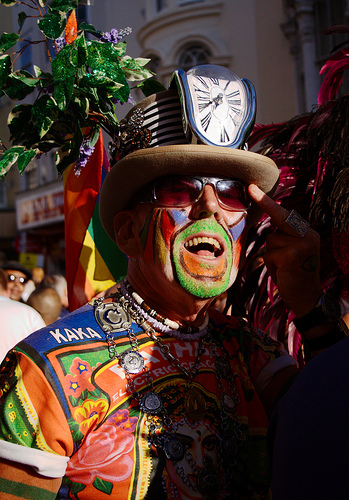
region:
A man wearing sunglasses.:
[149, 175, 240, 213]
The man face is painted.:
[148, 190, 247, 297]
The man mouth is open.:
[172, 229, 227, 266]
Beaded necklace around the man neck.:
[110, 292, 203, 354]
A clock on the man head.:
[172, 65, 256, 137]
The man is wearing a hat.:
[102, 84, 253, 175]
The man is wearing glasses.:
[3, 270, 23, 284]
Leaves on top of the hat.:
[44, 37, 139, 106]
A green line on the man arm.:
[8, 477, 38, 498]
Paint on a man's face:
[136, 163, 254, 299]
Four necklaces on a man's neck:
[91, 273, 241, 498]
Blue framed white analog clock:
[178, 63, 256, 148]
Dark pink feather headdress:
[236, 45, 347, 360]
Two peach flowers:
[63, 355, 92, 397]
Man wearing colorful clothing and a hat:
[0, 64, 347, 498]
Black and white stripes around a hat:
[141, 94, 189, 148]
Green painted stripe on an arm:
[0, 473, 62, 497]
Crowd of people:
[0, 255, 69, 370]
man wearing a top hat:
[97, 93, 278, 299]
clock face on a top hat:
[185, 59, 250, 146]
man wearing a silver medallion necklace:
[93, 295, 243, 492]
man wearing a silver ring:
[282, 210, 310, 239]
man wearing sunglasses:
[128, 171, 259, 212]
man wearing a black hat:
[1, 259, 34, 279]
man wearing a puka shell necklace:
[117, 278, 210, 340]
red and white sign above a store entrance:
[13, 182, 64, 224]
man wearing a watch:
[286, 291, 343, 337]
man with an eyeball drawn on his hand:
[300, 251, 321, 271]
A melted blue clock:
[170, 54, 258, 151]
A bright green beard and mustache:
[166, 210, 236, 302]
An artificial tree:
[0, 1, 157, 170]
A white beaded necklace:
[111, 272, 218, 345]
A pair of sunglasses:
[149, 179, 238, 213]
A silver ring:
[282, 202, 311, 241]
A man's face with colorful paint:
[123, 158, 251, 306]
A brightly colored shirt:
[2, 274, 347, 495]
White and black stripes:
[138, 95, 188, 151]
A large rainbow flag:
[57, 96, 133, 311]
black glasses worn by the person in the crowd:
[5, 272, 23, 285]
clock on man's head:
[162, 54, 256, 147]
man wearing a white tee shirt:
[0, 258, 46, 364]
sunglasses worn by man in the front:
[143, 166, 251, 212]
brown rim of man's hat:
[125, 145, 278, 189]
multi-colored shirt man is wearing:
[1, 283, 169, 498]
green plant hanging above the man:
[0, 33, 154, 178]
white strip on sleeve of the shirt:
[0, 436, 71, 476]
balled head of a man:
[25, 284, 60, 324]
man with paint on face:
[110, 143, 265, 317]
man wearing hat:
[173, 60, 244, 162]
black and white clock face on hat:
[178, 60, 261, 146]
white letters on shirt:
[52, 320, 102, 346]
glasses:
[145, 171, 252, 214]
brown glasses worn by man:
[147, 174, 232, 210]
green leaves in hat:
[47, 53, 82, 82]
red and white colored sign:
[15, 193, 62, 227]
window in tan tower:
[166, 37, 218, 66]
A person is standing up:
[26, 288, 67, 333]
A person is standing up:
[5, 263, 28, 301]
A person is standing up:
[24, 91, 317, 483]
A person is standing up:
[4, 274, 49, 351]